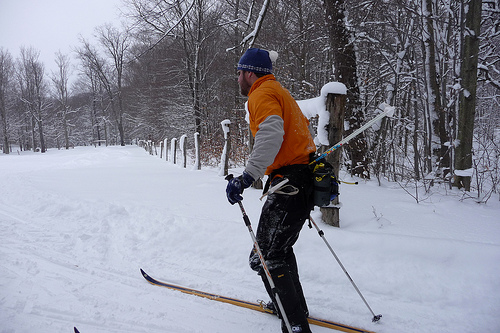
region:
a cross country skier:
[72, 47, 389, 330]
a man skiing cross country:
[223, 44, 330, 331]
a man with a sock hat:
[227, 42, 290, 99]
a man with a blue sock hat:
[231, 44, 279, 98]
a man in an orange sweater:
[240, 73, 320, 173]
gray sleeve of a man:
[244, 115, 284, 188]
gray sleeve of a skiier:
[235, 113, 286, 184]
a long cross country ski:
[139, 267, 371, 331]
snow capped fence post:
[317, 80, 350, 224]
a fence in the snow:
[127, 118, 241, 177]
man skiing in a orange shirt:
[170, 41, 459, 331]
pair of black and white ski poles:
[222, 170, 389, 331]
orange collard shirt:
[235, 77, 335, 170]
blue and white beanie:
[228, 40, 285, 78]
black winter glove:
[221, 165, 255, 206]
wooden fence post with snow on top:
[317, 75, 382, 242]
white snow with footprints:
[48, 187, 188, 262]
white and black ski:
[128, 257, 263, 321]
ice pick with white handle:
[247, 95, 417, 214]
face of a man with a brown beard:
[230, 60, 266, 103]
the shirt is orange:
[241, 78, 326, 154]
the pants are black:
[257, 183, 317, 318]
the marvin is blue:
[228, 48, 286, 78]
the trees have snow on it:
[155, 43, 231, 119]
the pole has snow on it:
[319, 83, 361, 200]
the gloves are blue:
[206, 175, 261, 207]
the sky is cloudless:
[25, 8, 91, 59]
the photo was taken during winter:
[3, 16, 498, 308]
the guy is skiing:
[185, 53, 418, 329]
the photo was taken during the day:
[3, 43, 488, 330]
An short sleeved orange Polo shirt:
[201, 85, 318, 170]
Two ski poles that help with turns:
[240, 186, 382, 326]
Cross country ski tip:
[112, 267, 263, 329]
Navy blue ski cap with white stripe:
[230, 37, 296, 72]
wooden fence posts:
[120, 113, 241, 168]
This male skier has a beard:
[216, 43, 263, 113]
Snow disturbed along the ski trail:
[6, 178, 142, 329]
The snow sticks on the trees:
[340, 28, 471, 185]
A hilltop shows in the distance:
[0, 67, 148, 142]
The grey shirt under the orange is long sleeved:
[199, 71, 349, 233]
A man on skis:
[115, 40, 420, 330]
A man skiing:
[135, 17, 385, 327]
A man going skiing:
[126, 26, 402, 326]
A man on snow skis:
[121, 16, 386, 323]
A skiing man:
[150, 23, 338, 324]